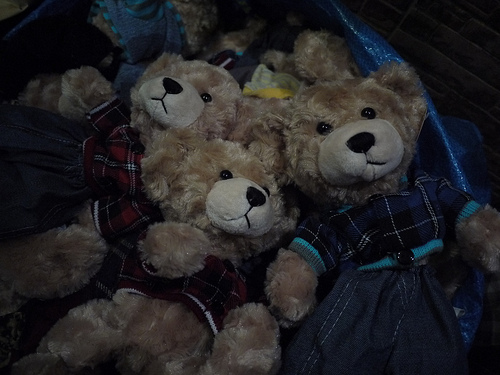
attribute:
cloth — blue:
[315, 3, 500, 344]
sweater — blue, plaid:
[287, 165, 486, 279]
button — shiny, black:
[396, 248, 416, 267]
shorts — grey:
[274, 260, 481, 374]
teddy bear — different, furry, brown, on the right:
[263, 59, 500, 373]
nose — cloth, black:
[346, 132, 377, 153]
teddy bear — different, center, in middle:
[13, 140, 302, 373]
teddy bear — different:
[3, 50, 264, 245]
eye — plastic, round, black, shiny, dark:
[317, 119, 334, 137]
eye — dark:
[363, 105, 378, 122]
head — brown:
[257, 61, 428, 204]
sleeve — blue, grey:
[287, 208, 343, 276]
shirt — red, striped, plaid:
[80, 93, 166, 243]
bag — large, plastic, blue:
[7, 3, 498, 374]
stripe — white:
[110, 286, 218, 337]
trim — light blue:
[456, 199, 483, 230]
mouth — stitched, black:
[357, 160, 387, 179]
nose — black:
[245, 183, 267, 210]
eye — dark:
[218, 167, 234, 179]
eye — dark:
[262, 183, 271, 197]